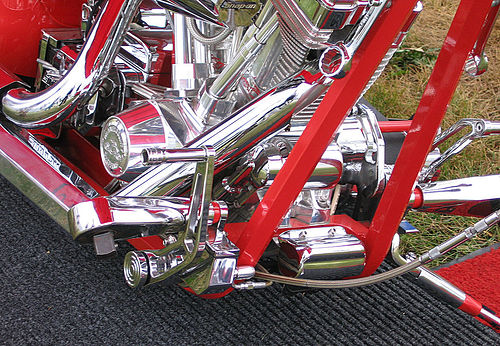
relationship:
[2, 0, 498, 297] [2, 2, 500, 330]
paint on motorcycle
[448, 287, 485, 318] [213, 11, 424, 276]
tape on bar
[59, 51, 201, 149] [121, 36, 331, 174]
reflection on chrome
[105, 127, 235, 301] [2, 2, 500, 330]
foot rest on motorcycle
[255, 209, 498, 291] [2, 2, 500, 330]
brake line on motorcycle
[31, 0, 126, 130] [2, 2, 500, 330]
exhaust tube on motorcycle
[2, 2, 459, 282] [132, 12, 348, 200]
motorcycle has suspension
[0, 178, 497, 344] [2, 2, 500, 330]
mat below motorcycle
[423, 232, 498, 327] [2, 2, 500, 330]
red mat below motorcycle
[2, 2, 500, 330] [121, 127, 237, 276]
motorcycle has break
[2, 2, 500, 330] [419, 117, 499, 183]
motorcycle has gear selector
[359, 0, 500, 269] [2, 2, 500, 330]
grass behind motorcycle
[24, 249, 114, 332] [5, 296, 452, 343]
grooves in carpet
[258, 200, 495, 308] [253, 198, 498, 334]
cable on bottom